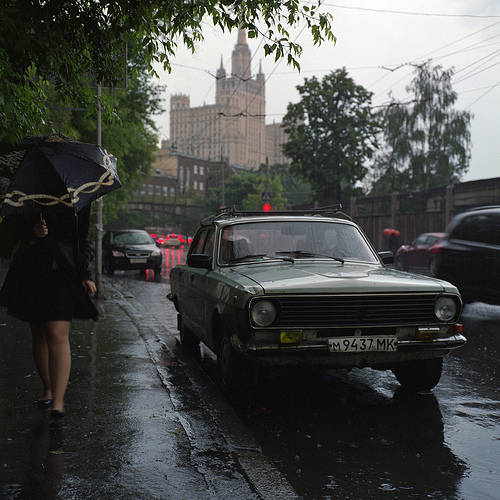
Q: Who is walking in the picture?
A: A woman.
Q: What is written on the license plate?
A: M9437MK.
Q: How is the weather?
A: Rainy.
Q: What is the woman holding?
A: An umbrella.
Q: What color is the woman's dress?
A: Black.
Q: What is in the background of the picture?
A: Buildings.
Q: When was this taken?
A: During the day.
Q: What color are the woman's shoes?
A: Black.